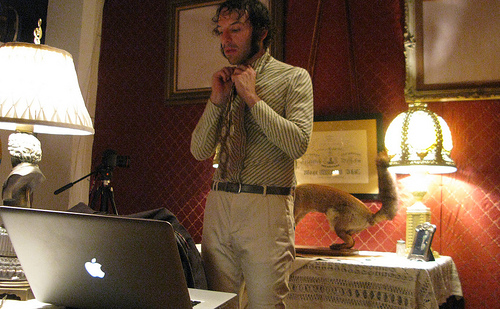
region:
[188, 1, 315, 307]
man adjusting his tie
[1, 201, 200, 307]
Apple laptop computer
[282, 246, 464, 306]
old lace embroidered table cloth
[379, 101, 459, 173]
gold gilded lamp shade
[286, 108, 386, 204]
framed document on wall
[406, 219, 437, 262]
old photograph in ornate frame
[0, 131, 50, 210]
sculptured lamp base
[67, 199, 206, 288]
piece of brown luggage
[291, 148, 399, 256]
animal preserved by taxidermy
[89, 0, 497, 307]
wrinkled red and gold wall covering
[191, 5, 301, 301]
man putting on a tie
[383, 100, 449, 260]
lamp on the table on the right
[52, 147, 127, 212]
video camera on a tripod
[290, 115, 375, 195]
diploma framed and on the wall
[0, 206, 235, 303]
apple laptop computer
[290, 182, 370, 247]
stuffed rabbit on a table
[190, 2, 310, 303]
man with a beard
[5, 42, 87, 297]
lamp beside the laptop computer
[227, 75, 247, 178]
patterned necktie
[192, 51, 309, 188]
green and white striped long sleeve dress shirt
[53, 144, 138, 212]
Black video camera for taking pictures.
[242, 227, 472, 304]
Table with white table cloth.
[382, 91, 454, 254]
Dome lampshade on lamp.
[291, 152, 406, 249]
Stuffed dead animal with long tail.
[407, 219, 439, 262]
Silver toned picture frame on table.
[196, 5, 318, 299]
Man trying to tie his tie.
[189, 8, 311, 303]
Green and beige long sleeve shirt with stripes.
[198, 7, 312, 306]
Plain khaki pants with side pockets.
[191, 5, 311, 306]
Unshaven man with side burns.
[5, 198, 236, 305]
Silver apple laptop for work.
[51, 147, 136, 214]
black camera next to the wal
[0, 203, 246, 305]
macbook in front of the man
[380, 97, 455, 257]
lamp on the table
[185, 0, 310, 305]
man wearing a tie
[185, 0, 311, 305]
young man wearing striped shirt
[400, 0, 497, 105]
frame on the wall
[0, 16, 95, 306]
lamp next to the macbook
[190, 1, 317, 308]
man wearing a belt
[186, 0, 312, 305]
Man tying his tie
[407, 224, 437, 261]
picture frame on the table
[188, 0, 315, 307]
a man getting dressed behind the computer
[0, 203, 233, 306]
an Apple computer in front of the man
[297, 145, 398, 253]
a small, stuffed animal behind the man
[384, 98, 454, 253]
a lit lamp behind the man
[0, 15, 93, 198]
a lit lamp to the left of the man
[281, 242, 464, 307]
a decorative tablecloth on the table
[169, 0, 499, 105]
picture frames on the wall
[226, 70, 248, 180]
a tie being tied by the man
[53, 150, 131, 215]
a camera on a tripod next to the man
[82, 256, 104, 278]
Apple logo on the computer